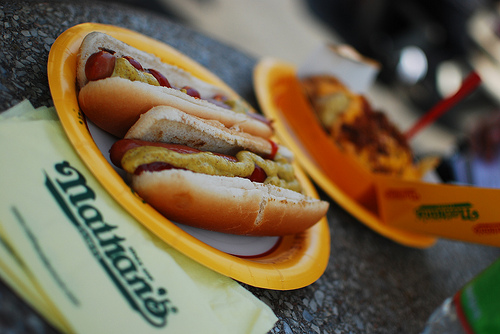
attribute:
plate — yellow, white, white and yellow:
[41, 19, 334, 294]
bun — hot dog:
[75, 30, 276, 151]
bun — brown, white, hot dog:
[119, 102, 329, 239]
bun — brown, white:
[72, 29, 278, 142]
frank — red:
[106, 135, 296, 184]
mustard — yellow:
[122, 142, 299, 189]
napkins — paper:
[3, 96, 287, 332]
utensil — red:
[399, 69, 483, 152]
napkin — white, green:
[4, 94, 279, 328]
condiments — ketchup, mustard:
[97, 44, 298, 193]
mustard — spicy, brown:
[116, 150, 297, 183]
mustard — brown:
[113, 142, 303, 185]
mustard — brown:
[107, 51, 169, 83]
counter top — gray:
[2, 0, 499, 331]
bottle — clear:
[418, 256, 498, 327]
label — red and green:
[455, 245, 498, 332]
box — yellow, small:
[270, 62, 499, 247]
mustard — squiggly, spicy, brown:
[116, 148, 302, 175]